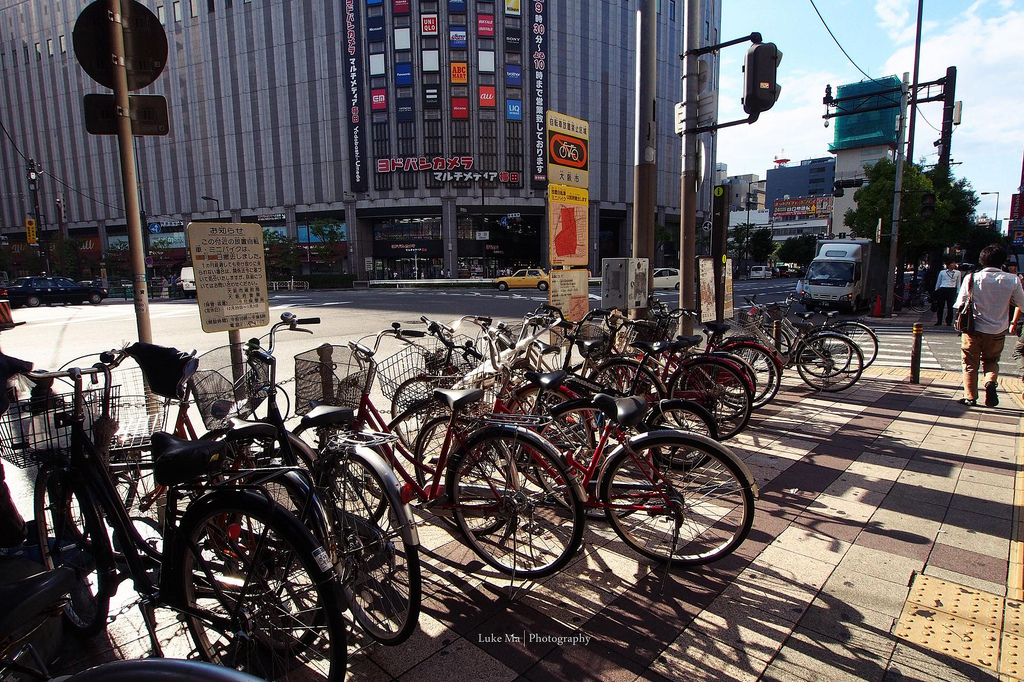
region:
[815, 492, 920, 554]
a shadow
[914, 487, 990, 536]
the sidewalk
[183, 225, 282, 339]
a sign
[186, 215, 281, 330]
a white sign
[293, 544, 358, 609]
a tire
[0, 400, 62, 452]
a basket on the bike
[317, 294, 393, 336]
the ground is grey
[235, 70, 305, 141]
a building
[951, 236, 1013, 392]
a person standing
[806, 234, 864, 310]
a white truck on the street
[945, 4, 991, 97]
white clouds in sky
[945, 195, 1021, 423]
man walking on sidewalk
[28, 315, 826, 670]
many bikes are parked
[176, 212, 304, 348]
black and white sign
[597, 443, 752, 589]
black tire on bike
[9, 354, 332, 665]
a two wheeled bicycle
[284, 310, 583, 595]
a two wheeled bicycle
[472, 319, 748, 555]
a two wheeled bicycle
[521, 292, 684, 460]
a two wheeled bicycle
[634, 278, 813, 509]
a two wheeled bicycle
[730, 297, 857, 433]
a two wheeled bicycle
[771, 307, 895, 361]
a two wheeled bicycle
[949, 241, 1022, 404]
woman carrying a brown bag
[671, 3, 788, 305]
traffic light on the metal pole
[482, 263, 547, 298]
yellow car on the road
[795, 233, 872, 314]
white truck beside the curb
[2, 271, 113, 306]
black car on the street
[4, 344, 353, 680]
bicycle with a black seat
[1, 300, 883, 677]
bicycles parked on the sidewalk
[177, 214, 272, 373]
white sign in front of the bicycles.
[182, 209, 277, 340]
white sign near a row of bikes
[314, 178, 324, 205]
glass window on the building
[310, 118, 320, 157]
glass window on the building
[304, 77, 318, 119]
glass window on the building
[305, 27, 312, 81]
glass window on the building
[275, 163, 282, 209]
glass window on the building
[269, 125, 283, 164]
glass window on the building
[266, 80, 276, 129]
glass window on the building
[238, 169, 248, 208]
glass window on the building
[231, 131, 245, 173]
glass window on the building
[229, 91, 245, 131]
glass window on the building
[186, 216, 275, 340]
white sign with black letters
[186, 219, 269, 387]
white sign attached to a post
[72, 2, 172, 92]
rear view of round traffic sign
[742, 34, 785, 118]
traffic light on side of street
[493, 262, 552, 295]
yellow car driving on the street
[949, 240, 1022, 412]
person carrying a brown handbag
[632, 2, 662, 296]
tall wooden utility pole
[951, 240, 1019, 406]
person walking on tan sidewalk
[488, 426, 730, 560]
a bike on the sidewalk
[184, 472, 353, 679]
a bike on the sidewalk